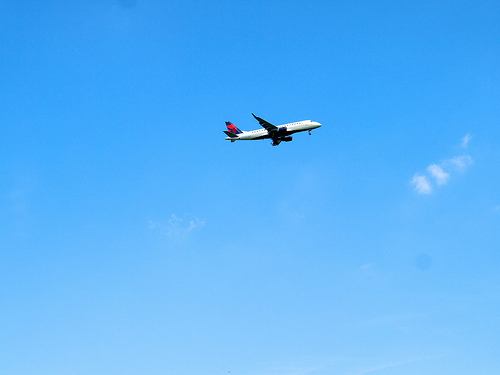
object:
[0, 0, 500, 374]
airplane sky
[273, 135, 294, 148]
wheel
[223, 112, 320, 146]
airplane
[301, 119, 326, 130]
nose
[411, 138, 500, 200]
clouds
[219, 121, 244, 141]
accents